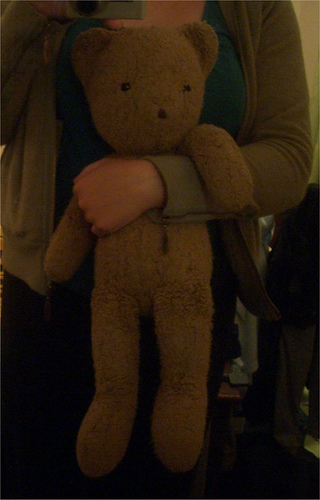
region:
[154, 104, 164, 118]
The teddy bears nose is brown.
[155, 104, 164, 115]
The teddy bears nose is small.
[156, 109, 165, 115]
The teddy bears nose is round.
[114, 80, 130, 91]
The teddy bears right eye is black.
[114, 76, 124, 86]
The teddy bears right eye small.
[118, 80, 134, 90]
The teddy bears right eye is small.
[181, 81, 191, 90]
The teddy bears left eye is small.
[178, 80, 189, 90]
The teddy bears left eye is black.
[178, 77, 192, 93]
The teddy bears left eye is round.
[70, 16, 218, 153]
The teddy bears face is brown.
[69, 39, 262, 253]
a brown teddy bear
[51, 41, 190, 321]
a teddy bear that is brown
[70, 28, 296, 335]
a stuffed bear that is brown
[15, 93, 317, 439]
a owman holding a bear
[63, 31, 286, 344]
a woman holding a teddy bear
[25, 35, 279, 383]
a woman holding a stuffed bear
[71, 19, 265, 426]
a woman holding a brown stuffed bear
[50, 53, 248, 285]
a stuffed bear inside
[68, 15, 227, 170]
head of a teddy bear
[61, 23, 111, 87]
ear of a teddy bear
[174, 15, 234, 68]
ear of a teddy bear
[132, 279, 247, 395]
leg of a teddy bear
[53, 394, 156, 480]
feet of a teddy bear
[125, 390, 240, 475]
feet of a teddy bear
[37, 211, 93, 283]
arm of a teddy bear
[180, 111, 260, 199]
arm of a teddy bear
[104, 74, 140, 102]
an eye of a teddy bear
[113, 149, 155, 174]
she's holding the bear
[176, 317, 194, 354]
the bear is brown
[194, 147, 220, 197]
bears arm is on hers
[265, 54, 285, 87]
the jacket is brown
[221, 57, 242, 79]
the shirt is teal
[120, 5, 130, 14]
the camera is silver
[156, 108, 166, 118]
the nose is brown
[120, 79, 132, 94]
the eye is black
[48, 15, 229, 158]
head of a teddy bear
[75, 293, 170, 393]
leg of a teddy bear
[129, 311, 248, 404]
leg of a teddy bear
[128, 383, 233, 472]
feet of a teddy bear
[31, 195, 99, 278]
arm of a teddy bear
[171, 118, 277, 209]
arm of a teddy bear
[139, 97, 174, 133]
nose of a teddy bear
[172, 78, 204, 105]
eye of a teddy bear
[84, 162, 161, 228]
hand of the person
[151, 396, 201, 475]
foot of the bear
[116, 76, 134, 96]
eye of a teddy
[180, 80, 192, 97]
eye of a teddy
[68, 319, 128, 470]
leg of a teddy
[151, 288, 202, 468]
leg of a teddy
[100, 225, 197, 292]
belly of a teddy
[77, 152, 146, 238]
hand of a woman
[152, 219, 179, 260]
string on a teddy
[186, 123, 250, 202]
arm of a teddy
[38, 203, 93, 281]
arm of a teddy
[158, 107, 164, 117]
Brown nose on a bear.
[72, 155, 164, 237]
A persons left hand.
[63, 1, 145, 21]
A grey and black camera.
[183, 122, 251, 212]
Brown teddy bear arm over a real arm.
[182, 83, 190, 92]
Smaller black eye on a bear.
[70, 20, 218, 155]
A brown teddy bear head.